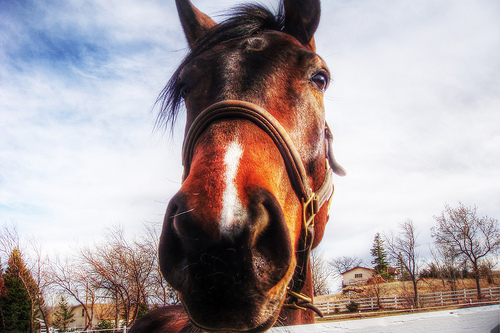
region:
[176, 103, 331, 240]
riding gear on the horse's face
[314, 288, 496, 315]
a white picket fence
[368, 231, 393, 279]
a tall evergreen tree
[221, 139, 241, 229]
white patch on the horses nose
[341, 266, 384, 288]
a house on the hill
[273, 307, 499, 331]
a white railing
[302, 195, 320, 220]
a brass buckle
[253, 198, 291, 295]
the horse's nostril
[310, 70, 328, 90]
brown eyes on the horse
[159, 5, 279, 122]
horse has black hair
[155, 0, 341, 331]
The horse gives a close up.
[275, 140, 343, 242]
The horses bridle.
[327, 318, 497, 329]
The fence keeps the horse in it's pasture.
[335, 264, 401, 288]
The house sits on the hill.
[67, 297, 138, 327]
The barn sits in the back.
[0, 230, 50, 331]
Trees are in the pasture.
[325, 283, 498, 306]
The white fence protects the horse.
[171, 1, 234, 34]
The horses ear.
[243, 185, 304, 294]
The horse's large nostril.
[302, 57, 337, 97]
The horse's calm eye.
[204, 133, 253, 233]
horse with a white patch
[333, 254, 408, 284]
house on the hill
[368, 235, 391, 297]
leaves on the tree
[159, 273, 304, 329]
horse with its mouth closed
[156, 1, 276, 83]
horse with black hair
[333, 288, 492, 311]
fence in front of the house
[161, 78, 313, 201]
strap on a horse face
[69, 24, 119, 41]
clouds in the sky.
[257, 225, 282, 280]
nostril of the horse.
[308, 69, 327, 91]
eye of the horse.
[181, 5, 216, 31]
ear of the horse.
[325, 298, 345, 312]
fence near the field.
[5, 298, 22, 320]
leaves on the tree.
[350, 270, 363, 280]
window on the house.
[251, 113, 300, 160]
strap on the horse's face.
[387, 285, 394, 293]
grass in the field.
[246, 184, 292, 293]
one dark left horse nostril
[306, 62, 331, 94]
one left brown horse eye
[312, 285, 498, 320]
long section of white wooden fence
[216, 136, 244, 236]
white patch on horse muzzle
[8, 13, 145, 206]
view of partially cloudy sky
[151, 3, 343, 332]
one large brown horse head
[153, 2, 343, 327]
one horse wearing halter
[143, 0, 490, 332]
horse standing at white wooden fence railing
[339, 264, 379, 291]
House with a pitched roof.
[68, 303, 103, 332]
A barn shaped building with rectangle window.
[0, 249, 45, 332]
Largest green and brown evergreen tree.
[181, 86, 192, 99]
Horse eyeball under the mane.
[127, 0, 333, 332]
A brown horse with white mark and black mane.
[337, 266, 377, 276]
A pitched red roof.